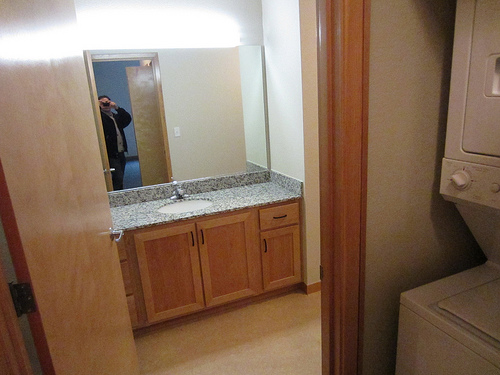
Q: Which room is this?
A: It is a bathroom.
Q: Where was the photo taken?
A: It was taken at the bathroom.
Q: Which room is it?
A: It is a bathroom.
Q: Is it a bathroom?
A: Yes, it is a bathroom.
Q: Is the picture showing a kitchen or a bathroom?
A: It is showing a bathroom.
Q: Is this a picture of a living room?
A: No, the picture is showing a bathroom.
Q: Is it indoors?
A: Yes, it is indoors.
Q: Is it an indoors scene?
A: Yes, it is indoors.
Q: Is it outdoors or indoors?
A: It is indoors.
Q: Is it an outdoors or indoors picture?
A: It is indoors.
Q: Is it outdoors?
A: No, it is indoors.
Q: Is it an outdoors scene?
A: No, it is indoors.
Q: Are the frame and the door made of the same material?
A: Yes, both the frame and the door are made of wood.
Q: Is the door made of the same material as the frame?
A: Yes, both the door and the frame are made of wood.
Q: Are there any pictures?
A: No, there are no pictures.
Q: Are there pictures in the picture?
A: No, there are no pictures.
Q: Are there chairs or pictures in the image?
A: No, there are no pictures or chairs.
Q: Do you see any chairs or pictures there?
A: No, there are no pictures or chairs.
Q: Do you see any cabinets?
A: Yes, there is a cabinet.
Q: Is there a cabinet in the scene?
A: Yes, there is a cabinet.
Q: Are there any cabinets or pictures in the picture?
A: Yes, there is a cabinet.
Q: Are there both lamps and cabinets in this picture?
A: No, there is a cabinet but no lamps.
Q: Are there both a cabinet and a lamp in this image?
A: No, there is a cabinet but no lamps.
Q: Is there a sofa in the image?
A: No, there are no sofas.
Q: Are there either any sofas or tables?
A: No, there are no sofas or tables.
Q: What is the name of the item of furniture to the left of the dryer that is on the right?
A: The piece of furniture is a cabinet.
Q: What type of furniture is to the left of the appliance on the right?
A: The piece of furniture is a cabinet.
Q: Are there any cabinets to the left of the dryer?
A: Yes, there is a cabinet to the left of the dryer.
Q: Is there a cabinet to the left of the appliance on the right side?
A: Yes, there is a cabinet to the left of the dryer.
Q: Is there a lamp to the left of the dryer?
A: No, there is a cabinet to the left of the dryer.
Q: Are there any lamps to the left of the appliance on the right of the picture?
A: No, there is a cabinet to the left of the dryer.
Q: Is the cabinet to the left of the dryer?
A: Yes, the cabinet is to the left of the dryer.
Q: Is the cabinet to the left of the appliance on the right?
A: Yes, the cabinet is to the left of the dryer.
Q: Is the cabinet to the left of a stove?
A: No, the cabinet is to the left of the dryer.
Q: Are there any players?
A: No, there are no players.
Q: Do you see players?
A: No, there are no players.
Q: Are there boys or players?
A: No, there are no players or boys.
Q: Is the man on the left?
A: Yes, the man is on the left of the image.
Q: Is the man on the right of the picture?
A: No, the man is on the left of the image.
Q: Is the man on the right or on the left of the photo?
A: The man is on the left of the image.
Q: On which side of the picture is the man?
A: The man is on the left of the image.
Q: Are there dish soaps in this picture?
A: No, there are no dish soaps.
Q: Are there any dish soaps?
A: No, there are no dish soaps.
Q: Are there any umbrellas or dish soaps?
A: No, there are no dish soaps or umbrellas.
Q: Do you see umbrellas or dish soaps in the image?
A: No, there are no dish soaps or umbrellas.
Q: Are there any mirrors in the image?
A: Yes, there is a mirror.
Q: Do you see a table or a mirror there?
A: Yes, there is a mirror.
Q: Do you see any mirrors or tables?
A: Yes, there is a mirror.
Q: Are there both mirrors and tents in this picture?
A: No, there is a mirror but no tents.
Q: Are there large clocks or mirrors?
A: Yes, there is a large mirror.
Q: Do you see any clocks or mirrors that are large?
A: Yes, the mirror is large.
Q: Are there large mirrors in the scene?
A: Yes, there is a large mirror.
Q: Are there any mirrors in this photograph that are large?
A: Yes, there is a mirror that is large.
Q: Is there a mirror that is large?
A: Yes, there is a mirror that is large.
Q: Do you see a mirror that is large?
A: Yes, there is a mirror that is large.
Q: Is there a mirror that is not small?
A: Yes, there is a large mirror.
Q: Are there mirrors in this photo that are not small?
A: Yes, there is a large mirror.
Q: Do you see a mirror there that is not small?
A: Yes, there is a large mirror.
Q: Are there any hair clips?
A: No, there are no hair clips.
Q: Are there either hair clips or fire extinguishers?
A: No, there are no hair clips or fire extinguishers.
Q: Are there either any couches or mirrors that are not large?
A: No, there is a mirror but it is large.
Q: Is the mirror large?
A: Yes, the mirror is large.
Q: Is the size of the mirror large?
A: Yes, the mirror is large.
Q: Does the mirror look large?
A: Yes, the mirror is large.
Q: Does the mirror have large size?
A: Yes, the mirror is large.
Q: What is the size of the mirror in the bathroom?
A: The mirror is large.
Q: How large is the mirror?
A: The mirror is large.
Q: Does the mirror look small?
A: No, the mirror is large.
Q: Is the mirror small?
A: No, the mirror is large.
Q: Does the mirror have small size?
A: No, the mirror is large.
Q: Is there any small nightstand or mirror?
A: No, there is a mirror but it is large.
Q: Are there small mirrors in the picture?
A: No, there is a mirror but it is large.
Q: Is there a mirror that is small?
A: No, there is a mirror but it is large.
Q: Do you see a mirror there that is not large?
A: No, there is a mirror but it is large.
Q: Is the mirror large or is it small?
A: The mirror is large.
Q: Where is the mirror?
A: The mirror is in the bathroom.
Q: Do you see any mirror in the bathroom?
A: Yes, there is a mirror in the bathroom.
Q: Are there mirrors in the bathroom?
A: Yes, there is a mirror in the bathroom.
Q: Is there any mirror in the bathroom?
A: Yes, there is a mirror in the bathroom.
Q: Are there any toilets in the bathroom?
A: No, there is a mirror in the bathroom.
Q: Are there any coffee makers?
A: No, there are no coffee makers.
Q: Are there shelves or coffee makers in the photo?
A: No, there are no coffee makers or shelves.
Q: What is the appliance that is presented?
A: The appliance is a dryer.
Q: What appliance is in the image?
A: The appliance is a dryer.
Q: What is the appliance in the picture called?
A: The appliance is a dryer.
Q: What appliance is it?
A: The appliance is a dryer.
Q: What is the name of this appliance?
A: This is a dryer.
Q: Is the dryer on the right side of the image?
A: Yes, the dryer is on the right of the image.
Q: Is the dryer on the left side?
A: No, the dryer is on the right of the image.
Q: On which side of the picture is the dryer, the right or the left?
A: The dryer is on the right of the image.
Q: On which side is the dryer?
A: The dryer is on the right of the image.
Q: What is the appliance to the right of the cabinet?
A: The appliance is a dryer.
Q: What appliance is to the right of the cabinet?
A: The appliance is a dryer.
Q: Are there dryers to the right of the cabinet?
A: Yes, there is a dryer to the right of the cabinet.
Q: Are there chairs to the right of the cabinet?
A: No, there is a dryer to the right of the cabinet.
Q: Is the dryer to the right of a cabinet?
A: Yes, the dryer is to the right of a cabinet.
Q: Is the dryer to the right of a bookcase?
A: No, the dryer is to the right of a cabinet.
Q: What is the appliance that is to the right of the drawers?
A: The appliance is a dryer.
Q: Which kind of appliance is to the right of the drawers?
A: The appliance is a dryer.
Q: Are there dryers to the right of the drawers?
A: Yes, there is a dryer to the right of the drawers.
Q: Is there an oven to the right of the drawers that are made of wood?
A: No, there is a dryer to the right of the drawers.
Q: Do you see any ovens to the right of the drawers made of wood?
A: No, there is a dryer to the right of the drawers.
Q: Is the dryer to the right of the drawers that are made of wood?
A: Yes, the dryer is to the right of the drawers.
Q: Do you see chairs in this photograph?
A: No, there are no chairs.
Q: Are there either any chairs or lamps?
A: No, there are no chairs or lamps.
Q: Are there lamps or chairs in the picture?
A: No, there are no chairs or lamps.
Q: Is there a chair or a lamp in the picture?
A: No, there are no chairs or lamps.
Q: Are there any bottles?
A: No, there are no bottles.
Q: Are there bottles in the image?
A: No, there are no bottles.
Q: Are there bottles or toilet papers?
A: No, there are no bottles or toilet papers.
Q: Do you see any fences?
A: No, there are no fences.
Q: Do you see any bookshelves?
A: No, there are no bookshelves.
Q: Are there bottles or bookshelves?
A: No, there are no bookshelves or bottles.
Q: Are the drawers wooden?
A: Yes, the drawers are wooden.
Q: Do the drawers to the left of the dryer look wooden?
A: Yes, the drawers are wooden.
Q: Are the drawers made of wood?
A: Yes, the drawers are made of wood.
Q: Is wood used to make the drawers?
A: Yes, the drawers are made of wood.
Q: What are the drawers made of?
A: The drawers are made of wood.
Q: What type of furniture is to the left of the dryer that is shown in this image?
A: The pieces of furniture are drawers.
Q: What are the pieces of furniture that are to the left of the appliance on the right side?
A: The pieces of furniture are drawers.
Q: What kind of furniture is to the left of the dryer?
A: The pieces of furniture are drawers.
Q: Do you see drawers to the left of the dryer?
A: Yes, there are drawers to the left of the dryer.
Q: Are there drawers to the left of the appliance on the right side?
A: Yes, there are drawers to the left of the dryer.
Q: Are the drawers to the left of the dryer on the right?
A: Yes, the drawers are to the left of the dryer.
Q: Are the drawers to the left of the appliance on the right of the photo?
A: Yes, the drawers are to the left of the dryer.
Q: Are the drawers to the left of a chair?
A: No, the drawers are to the left of the dryer.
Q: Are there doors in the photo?
A: Yes, there is a door.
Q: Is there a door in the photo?
A: Yes, there is a door.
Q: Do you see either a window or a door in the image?
A: Yes, there is a door.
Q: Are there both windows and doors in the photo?
A: No, there is a door but no windows.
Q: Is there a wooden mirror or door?
A: Yes, there is a wood door.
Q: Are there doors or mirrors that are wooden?
A: Yes, the door is wooden.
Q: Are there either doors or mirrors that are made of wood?
A: Yes, the door is made of wood.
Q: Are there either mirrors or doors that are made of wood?
A: Yes, the door is made of wood.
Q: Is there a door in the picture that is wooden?
A: Yes, there is a wood door.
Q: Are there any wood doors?
A: Yes, there is a wood door.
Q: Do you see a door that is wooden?
A: Yes, there is a door that is wooden.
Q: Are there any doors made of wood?
A: Yes, there is a door that is made of wood.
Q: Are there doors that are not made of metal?
A: Yes, there is a door that is made of wood.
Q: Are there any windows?
A: No, there are no windows.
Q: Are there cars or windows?
A: No, there are no windows or cars.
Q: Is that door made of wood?
A: Yes, the door is made of wood.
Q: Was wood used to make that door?
A: Yes, the door is made of wood.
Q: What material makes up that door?
A: The door is made of wood.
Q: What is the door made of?
A: The door is made of wood.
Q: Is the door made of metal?
A: No, the door is made of wood.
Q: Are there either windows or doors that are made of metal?
A: No, there is a door but it is made of wood.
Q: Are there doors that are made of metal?
A: No, there is a door but it is made of wood.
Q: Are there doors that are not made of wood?
A: No, there is a door but it is made of wood.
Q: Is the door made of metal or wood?
A: The door is made of wood.